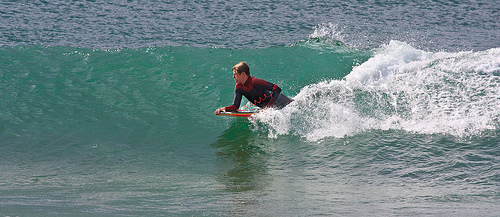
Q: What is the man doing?
A: Surfing.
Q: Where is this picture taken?
A: The ocean.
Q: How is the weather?
A: Sunny.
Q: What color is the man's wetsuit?
A: Orange and black.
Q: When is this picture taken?
A: Daytime.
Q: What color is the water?
A: Blue.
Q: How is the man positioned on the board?
A: He is laying down.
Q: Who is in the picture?
A: A man.